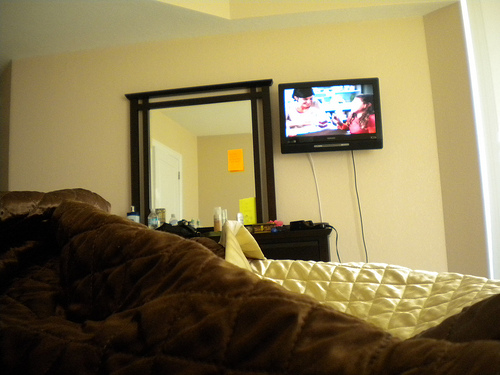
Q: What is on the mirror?
A: An orange note.